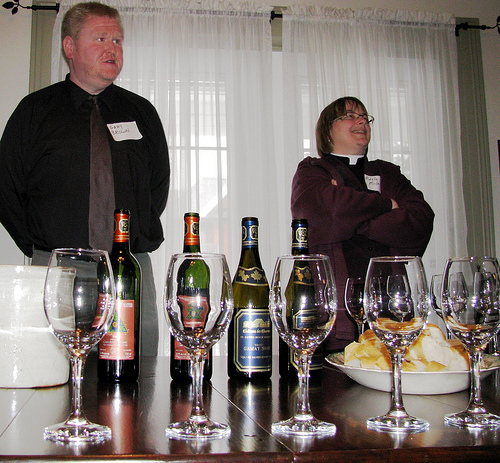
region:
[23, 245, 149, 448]
a wine glass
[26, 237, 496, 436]
five wine glasses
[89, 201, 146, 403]
a bottle of wine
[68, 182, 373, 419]
four bottles of wine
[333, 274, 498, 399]
a bowl of bread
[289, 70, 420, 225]
a woman wearing glasses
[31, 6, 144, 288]
a man wearing a tie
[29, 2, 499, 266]
white curtains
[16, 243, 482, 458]
a wooden table with wine on it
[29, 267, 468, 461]
a wooden table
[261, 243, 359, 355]
glass on the table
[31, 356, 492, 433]
handle of the glasses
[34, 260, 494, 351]
five glasses on the table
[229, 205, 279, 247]
top of the bottle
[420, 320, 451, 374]
food in a bowl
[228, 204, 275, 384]
green bottle with blue sticker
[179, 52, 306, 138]
curtains on the window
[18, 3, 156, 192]
man with a tie on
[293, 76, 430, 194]
lady with glasses on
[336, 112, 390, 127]
glasses on the woman's face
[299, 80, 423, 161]
a woman wearing glasses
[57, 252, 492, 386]
empty wine glasses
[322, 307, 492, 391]
a plate of food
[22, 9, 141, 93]
a man with short hair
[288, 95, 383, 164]
a woman with short hair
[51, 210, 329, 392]
four wine bottles on a table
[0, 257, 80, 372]
a white canister on a table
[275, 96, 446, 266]
a woman with her arms crossed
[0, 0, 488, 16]
a long curtain rod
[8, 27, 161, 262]
a man with his hands behind his back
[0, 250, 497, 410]
five empty wine glasses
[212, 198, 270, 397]
a wine bottle with a blue label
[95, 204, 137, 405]
a wine bottle with a red label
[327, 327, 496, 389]
a bowl of food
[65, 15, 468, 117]
a window covered with white curtains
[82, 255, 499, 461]
wine glasses sitting on a table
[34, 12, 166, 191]
a man wearing a white name tag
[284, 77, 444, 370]
a woman wearing glasses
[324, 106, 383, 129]
the glasses on the woman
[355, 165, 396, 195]
the name tag on the woman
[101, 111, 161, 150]
the name tag on the man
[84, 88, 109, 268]
the tie on the man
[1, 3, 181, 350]
a tall man standing next to a woman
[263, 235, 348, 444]
the wine glass in the middle of the front row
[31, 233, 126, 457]
the wine glass on the left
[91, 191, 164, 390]
the wine bottle on the left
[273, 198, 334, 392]
the wine bottle on the right